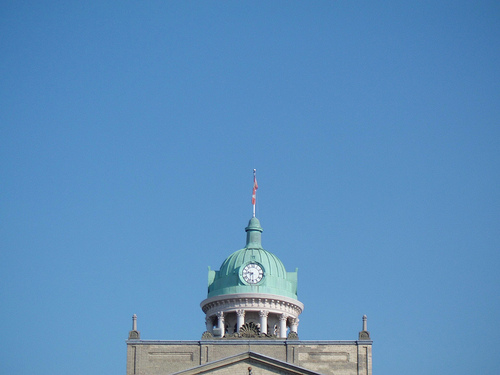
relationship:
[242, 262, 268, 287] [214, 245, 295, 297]
clock on dome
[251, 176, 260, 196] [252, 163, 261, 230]
flag on pole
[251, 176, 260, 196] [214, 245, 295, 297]
flag on dome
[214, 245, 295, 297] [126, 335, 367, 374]
dome on top of building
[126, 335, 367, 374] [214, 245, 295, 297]
building below dome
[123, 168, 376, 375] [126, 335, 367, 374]
building on building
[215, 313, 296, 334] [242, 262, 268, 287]
columns below clock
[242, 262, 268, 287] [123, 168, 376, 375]
clock on building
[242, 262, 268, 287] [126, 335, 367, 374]
clock on building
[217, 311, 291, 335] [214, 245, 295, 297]
pillars around dome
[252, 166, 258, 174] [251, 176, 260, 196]
ball on flag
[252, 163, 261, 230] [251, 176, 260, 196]
pole of flag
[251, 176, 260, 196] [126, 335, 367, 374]
flag on building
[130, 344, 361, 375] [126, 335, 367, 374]
wall of building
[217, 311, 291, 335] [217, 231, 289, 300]
pillars on roof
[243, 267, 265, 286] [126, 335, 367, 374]
roman numerals on building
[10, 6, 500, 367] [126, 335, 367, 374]
sky above building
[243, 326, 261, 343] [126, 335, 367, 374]
design on building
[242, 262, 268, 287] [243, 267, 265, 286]
clock has roman numerals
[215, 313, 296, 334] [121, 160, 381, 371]
columns on front